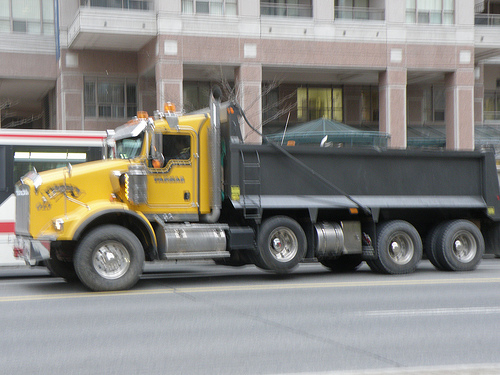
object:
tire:
[254, 213, 308, 271]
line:
[355, 306, 498, 319]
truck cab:
[11, 99, 216, 240]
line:
[0, 277, 499, 302]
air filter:
[128, 162, 149, 202]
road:
[0, 258, 499, 373]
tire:
[433, 218, 486, 272]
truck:
[12, 84, 500, 291]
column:
[155, 35, 182, 117]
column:
[233, 63, 260, 146]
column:
[378, 69, 406, 149]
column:
[443, 70, 475, 150]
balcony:
[65, 0, 157, 51]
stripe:
[0, 134, 107, 139]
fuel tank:
[155, 223, 230, 259]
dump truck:
[13, 101, 499, 290]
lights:
[136, 109, 149, 118]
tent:
[264, 117, 389, 144]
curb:
[0, 257, 214, 278]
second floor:
[0, 0, 499, 51]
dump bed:
[221, 101, 499, 223]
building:
[1, 0, 499, 192]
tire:
[73, 223, 146, 290]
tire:
[370, 219, 424, 274]